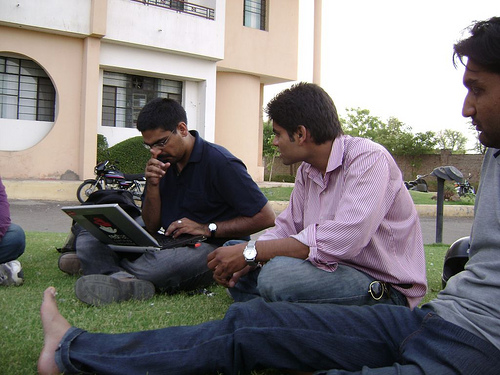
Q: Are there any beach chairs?
A: No, there are no beach chairs.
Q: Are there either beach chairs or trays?
A: No, there are no beach chairs or trays.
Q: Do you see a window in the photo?
A: Yes, there is a window.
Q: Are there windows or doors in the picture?
A: Yes, there is a window.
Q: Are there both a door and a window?
A: No, there is a window but no doors.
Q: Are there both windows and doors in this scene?
A: No, there is a window but no doors.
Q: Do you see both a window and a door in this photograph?
A: No, there is a window but no doors.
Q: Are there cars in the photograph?
A: No, there are no cars.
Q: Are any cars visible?
A: No, there are no cars.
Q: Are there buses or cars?
A: No, there are no cars or buses.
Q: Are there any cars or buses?
A: No, there are no cars or buses.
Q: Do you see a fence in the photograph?
A: No, there are no fences.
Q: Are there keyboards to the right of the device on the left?
A: No, there is a man to the right of the laptop.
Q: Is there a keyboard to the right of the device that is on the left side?
A: No, there is a man to the right of the laptop.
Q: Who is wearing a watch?
A: The man is wearing a watch.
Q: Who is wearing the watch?
A: The man is wearing a watch.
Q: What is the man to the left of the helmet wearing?
A: The man is wearing a watch.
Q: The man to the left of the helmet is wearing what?
A: The man is wearing a watch.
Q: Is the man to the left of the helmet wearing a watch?
A: Yes, the man is wearing a watch.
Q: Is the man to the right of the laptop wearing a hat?
A: No, the man is wearing a watch.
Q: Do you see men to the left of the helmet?
A: Yes, there is a man to the left of the helmet.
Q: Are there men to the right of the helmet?
A: No, the man is to the left of the helmet.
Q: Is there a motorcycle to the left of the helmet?
A: No, there is a man to the left of the helmet.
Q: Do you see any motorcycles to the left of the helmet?
A: No, there is a man to the left of the helmet.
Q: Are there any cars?
A: No, there are no cars.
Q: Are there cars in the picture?
A: No, there are no cars.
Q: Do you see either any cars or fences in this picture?
A: No, there are no cars or fences.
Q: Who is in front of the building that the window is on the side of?
A: The people are in front of the building.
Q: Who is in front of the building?
A: The people are in front of the building.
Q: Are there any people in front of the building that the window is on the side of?
A: Yes, there are people in front of the building.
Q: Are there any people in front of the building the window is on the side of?
A: Yes, there are people in front of the building.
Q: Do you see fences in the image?
A: No, there are no fences.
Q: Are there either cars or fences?
A: No, there are no fences or cars.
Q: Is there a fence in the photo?
A: No, there are no fences.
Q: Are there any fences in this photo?
A: No, there are no fences.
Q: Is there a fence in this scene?
A: No, there are no fences.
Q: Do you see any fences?
A: No, there are no fences.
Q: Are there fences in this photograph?
A: No, there are no fences.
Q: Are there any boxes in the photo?
A: No, there are no boxes.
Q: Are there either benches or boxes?
A: No, there are no boxes or benches.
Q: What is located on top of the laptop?
A: The sticker is on top of the laptop.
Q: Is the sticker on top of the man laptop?
A: Yes, the sticker is on top of the laptop.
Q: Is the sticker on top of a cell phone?
A: No, the sticker is on top of the laptop.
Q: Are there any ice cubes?
A: No, there are no ice cubes.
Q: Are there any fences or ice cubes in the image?
A: No, there are no ice cubes or fences.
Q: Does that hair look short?
A: Yes, the hair is short.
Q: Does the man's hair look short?
A: Yes, the hair is short.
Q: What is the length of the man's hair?
A: The hair is short.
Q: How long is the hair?
A: The hair is short.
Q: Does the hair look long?
A: No, the hair is short.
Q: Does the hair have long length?
A: No, the hair is short.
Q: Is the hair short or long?
A: The hair is short.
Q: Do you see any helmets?
A: Yes, there is a helmet.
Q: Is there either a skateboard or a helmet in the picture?
A: Yes, there is a helmet.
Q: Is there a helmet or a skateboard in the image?
A: Yes, there is a helmet.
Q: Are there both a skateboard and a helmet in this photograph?
A: No, there is a helmet but no skateboards.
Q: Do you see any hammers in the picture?
A: No, there are no hammers.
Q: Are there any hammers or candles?
A: No, there are no hammers or candles.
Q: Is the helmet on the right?
A: Yes, the helmet is on the right of the image.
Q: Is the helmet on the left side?
A: No, the helmet is on the right of the image.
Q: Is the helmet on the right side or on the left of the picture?
A: The helmet is on the right of the image.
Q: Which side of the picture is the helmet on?
A: The helmet is on the right of the image.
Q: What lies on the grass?
A: The helmet lies on the grass.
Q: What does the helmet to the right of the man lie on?
A: The helmet lies on the grass.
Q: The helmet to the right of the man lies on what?
A: The helmet lies on the grass.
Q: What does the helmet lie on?
A: The helmet lies on the grass.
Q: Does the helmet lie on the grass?
A: Yes, the helmet lies on the grass.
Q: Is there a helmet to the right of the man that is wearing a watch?
A: Yes, there is a helmet to the right of the man.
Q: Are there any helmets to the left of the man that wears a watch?
A: No, the helmet is to the right of the man.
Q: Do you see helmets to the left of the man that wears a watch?
A: No, the helmet is to the right of the man.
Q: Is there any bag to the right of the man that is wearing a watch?
A: No, there is a helmet to the right of the man.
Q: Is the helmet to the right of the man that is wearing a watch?
A: Yes, the helmet is to the right of the man.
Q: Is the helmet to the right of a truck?
A: No, the helmet is to the right of the man.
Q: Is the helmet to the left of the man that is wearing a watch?
A: No, the helmet is to the right of the man.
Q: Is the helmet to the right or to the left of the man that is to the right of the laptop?
A: The helmet is to the right of the man.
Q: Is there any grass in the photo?
A: Yes, there is grass.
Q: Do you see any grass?
A: Yes, there is grass.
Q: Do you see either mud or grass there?
A: Yes, there is grass.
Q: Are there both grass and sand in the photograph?
A: No, there is grass but no sand.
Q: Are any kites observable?
A: No, there are no kites.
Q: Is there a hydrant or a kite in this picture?
A: No, there are no kites or fire hydrants.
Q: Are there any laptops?
A: Yes, there is a laptop.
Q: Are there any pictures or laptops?
A: Yes, there is a laptop.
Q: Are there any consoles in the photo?
A: No, there are no consoles.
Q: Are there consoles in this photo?
A: No, there are no consoles.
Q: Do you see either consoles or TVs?
A: No, there are no consoles or tvs.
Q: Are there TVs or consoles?
A: No, there are no consoles or tvs.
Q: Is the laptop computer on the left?
A: Yes, the laptop computer is on the left of the image.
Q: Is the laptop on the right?
A: No, the laptop is on the left of the image.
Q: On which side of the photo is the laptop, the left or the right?
A: The laptop is on the left of the image.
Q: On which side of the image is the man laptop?
A: The laptop is on the left of the image.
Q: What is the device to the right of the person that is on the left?
A: The device is a laptop.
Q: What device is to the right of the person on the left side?
A: The device is a laptop.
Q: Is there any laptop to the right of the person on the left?
A: Yes, there is a laptop to the right of the person.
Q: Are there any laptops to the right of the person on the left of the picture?
A: Yes, there is a laptop to the right of the person.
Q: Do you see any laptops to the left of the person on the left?
A: No, the laptop is to the right of the person.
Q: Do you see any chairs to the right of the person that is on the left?
A: No, there is a laptop to the right of the person.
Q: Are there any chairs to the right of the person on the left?
A: No, there is a laptop to the right of the person.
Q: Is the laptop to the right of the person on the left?
A: Yes, the laptop is to the right of the person.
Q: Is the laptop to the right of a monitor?
A: No, the laptop is to the right of the person.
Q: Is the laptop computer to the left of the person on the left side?
A: No, the laptop computer is to the right of the person.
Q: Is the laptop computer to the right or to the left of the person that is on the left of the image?
A: The laptop computer is to the right of the person.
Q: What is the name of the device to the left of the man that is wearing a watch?
A: The device is a laptop.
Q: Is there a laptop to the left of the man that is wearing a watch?
A: Yes, there is a laptop to the left of the man.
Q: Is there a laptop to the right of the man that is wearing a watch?
A: No, the laptop is to the left of the man.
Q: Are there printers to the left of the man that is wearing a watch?
A: No, there is a laptop to the left of the man.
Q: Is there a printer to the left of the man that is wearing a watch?
A: No, there is a laptop to the left of the man.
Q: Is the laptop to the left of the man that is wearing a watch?
A: Yes, the laptop is to the left of the man.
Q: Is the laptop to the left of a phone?
A: No, the laptop is to the left of the man.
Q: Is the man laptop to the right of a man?
A: No, the laptop is to the left of a man.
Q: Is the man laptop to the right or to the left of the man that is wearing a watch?
A: The laptop is to the left of the man.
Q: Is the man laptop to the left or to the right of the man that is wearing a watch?
A: The laptop is to the left of the man.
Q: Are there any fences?
A: No, there are no fences.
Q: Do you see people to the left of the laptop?
A: Yes, there is a person to the left of the laptop.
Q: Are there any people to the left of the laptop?
A: Yes, there is a person to the left of the laptop.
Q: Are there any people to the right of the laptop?
A: No, the person is to the left of the laptop.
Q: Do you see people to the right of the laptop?
A: No, the person is to the left of the laptop.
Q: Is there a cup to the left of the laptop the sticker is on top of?
A: No, there is a person to the left of the laptop.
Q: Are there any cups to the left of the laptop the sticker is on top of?
A: No, there is a person to the left of the laptop.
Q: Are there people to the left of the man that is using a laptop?
A: Yes, there is a person to the left of the man.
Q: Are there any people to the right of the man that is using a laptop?
A: No, the person is to the left of the man.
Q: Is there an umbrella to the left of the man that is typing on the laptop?
A: No, there is a person to the left of the man.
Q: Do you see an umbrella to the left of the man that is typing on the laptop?
A: No, there is a person to the left of the man.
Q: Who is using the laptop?
A: The man is using the laptop.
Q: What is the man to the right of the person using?
A: The man is using a laptop computer.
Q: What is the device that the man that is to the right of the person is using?
A: The device is a laptop.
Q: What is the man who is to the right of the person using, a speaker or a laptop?
A: The man is using a laptop.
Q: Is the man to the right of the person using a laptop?
A: Yes, the man is using a laptop.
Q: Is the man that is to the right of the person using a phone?
A: No, the man is using a laptop.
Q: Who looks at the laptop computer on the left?
A: The man looks at the laptop computer.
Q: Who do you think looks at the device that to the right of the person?
A: The man looks at the laptop computer.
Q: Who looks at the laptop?
A: The man looks at the laptop computer.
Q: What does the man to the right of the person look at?
A: The man looks at the laptop.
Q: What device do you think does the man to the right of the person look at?
A: The man looks at the laptop.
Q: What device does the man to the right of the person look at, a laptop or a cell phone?
A: The man looks at a laptop.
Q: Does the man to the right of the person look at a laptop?
A: Yes, the man looks at a laptop.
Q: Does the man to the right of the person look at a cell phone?
A: No, the man looks at a laptop.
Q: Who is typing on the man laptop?
A: The man is typing on the laptop.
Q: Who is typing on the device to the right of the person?
A: The man is typing on the laptop.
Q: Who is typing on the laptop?
A: The man is typing on the laptop.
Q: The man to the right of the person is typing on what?
A: The man is typing on the laptop.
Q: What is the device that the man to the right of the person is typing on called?
A: The device is a laptop.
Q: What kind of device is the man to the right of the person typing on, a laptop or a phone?
A: The man is typing on a laptop.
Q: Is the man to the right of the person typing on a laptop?
A: Yes, the man is typing on a laptop.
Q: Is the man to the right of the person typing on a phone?
A: No, the man is typing on a laptop.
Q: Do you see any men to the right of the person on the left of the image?
A: Yes, there is a man to the right of the person.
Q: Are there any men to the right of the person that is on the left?
A: Yes, there is a man to the right of the person.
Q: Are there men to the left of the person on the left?
A: No, the man is to the right of the person.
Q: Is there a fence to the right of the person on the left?
A: No, there is a man to the right of the person.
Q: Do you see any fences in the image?
A: No, there are no fences.